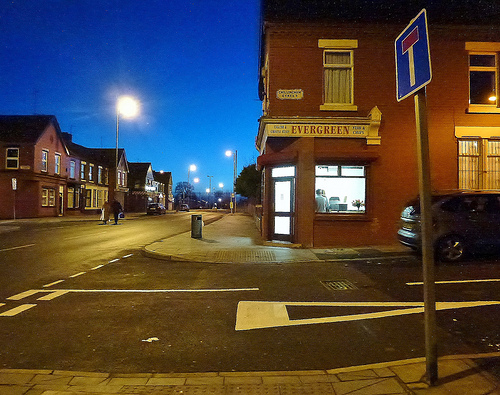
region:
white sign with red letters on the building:
[253, 116, 382, 152]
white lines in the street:
[231, 294, 499, 334]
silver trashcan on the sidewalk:
[187, 210, 205, 242]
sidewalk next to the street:
[145, 208, 409, 268]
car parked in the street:
[395, 184, 497, 262]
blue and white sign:
[391, 5, 436, 105]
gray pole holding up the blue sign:
[412, 88, 440, 387]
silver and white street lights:
[107, 90, 241, 213]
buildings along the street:
[1, 110, 174, 224]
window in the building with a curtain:
[311, 35, 361, 114]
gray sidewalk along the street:
[1, 349, 498, 393]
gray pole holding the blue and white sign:
[411, 91, 436, 386]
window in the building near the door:
[311, 157, 371, 222]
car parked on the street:
[396, 180, 499, 260]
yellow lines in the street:
[1, 225, 113, 255]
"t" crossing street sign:
[385, 7, 467, 389]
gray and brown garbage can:
[183, 208, 207, 245]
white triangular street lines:
[230, 280, 492, 335]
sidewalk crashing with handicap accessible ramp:
[139, 237, 291, 272]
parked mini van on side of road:
[401, 177, 498, 257]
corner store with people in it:
[251, 121, 388, 252]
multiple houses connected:
[5, 108, 170, 218]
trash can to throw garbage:
[185, 208, 210, 245]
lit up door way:
[262, 161, 302, 245]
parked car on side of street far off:
[141, 200, 171, 217]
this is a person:
[95, 195, 106, 220]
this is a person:
[100, 191, 120, 221]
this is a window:
[27, 146, 48, 172]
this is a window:
[51, 145, 68, 181]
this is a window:
[318, 163, 372, 215]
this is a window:
[2, 145, 25, 175]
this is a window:
[93, 162, 111, 185]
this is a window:
[43, 183, 58, 208]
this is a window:
[314, 50, 356, 115]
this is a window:
[458, 48, 498, 108]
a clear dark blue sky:
[148, 38, 208, 123]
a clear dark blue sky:
[163, 61, 225, 142]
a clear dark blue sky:
[51, 26, 123, 66]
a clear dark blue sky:
[169, 43, 228, 104]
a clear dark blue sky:
[93, 37, 149, 75]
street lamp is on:
[95, 59, 155, 280]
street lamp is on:
[182, 152, 206, 193]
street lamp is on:
[194, 129, 253, 181]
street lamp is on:
[222, 127, 252, 228]